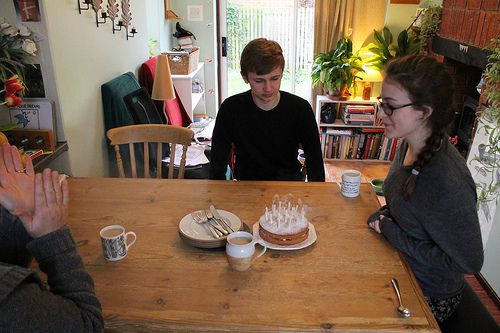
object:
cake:
[259, 209, 310, 245]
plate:
[250, 225, 320, 255]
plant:
[310, 38, 367, 101]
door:
[217, 0, 315, 106]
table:
[29, 176, 442, 333]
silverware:
[191, 205, 234, 239]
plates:
[178, 209, 244, 248]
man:
[208, 38, 325, 182]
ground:
[358, 68, 413, 133]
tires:
[141, 166, 408, 306]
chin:
[385, 130, 402, 138]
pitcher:
[226, 227, 263, 274]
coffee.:
[99, 225, 137, 262]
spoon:
[390, 278, 411, 318]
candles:
[277, 217, 280, 228]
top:
[259, 210, 309, 236]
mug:
[334, 169, 362, 197]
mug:
[226, 231, 267, 271]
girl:
[366, 50, 483, 324]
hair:
[385, 54, 456, 202]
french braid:
[386, 54, 455, 200]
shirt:
[366, 130, 483, 298]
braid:
[400, 60, 454, 198]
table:
[40, 176, 439, 331]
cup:
[99, 225, 137, 262]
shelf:
[316, 94, 403, 163]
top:
[209, 89, 326, 182]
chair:
[106, 123, 194, 179]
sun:
[220, 5, 312, 106]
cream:
[230, 236, 252, 244]